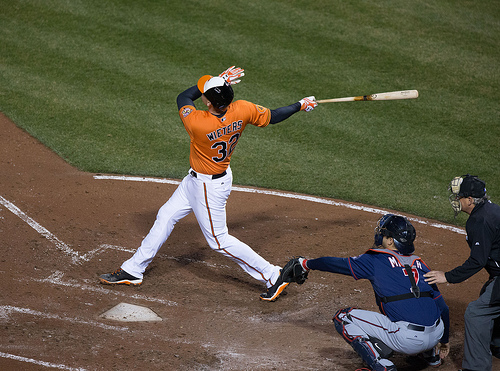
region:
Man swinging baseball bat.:
[273, 90, 402, 160]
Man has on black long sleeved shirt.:
[262, 102, 312, 155]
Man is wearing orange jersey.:
[186, 111, 245, 201]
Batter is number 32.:
[207, 112, 262, 226]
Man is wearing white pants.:
[166, 196, 241, 268]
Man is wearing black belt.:
[174, 161, 232, 211]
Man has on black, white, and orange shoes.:
[93, 255, 142, 312]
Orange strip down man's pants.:
[203, 188, 247, 323]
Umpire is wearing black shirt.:
[456, 196, 489, 314]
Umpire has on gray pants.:
[458, 292, 484, 344]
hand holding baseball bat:
[278, 48, 440, 150]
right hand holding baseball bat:
[281, 68, 446, 130]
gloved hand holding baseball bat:
[267, 68, 444, 145]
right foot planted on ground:
[85, 258, 152, 300]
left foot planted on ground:
[252, 248, 292, 324]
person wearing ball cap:
[192, 68, 238, 116]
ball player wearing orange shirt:
[166, 88, 278, 185]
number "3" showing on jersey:
[210, 136, 230, 172]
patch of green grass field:
[7, 2, 148, 131]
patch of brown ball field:
[14, 151, 79, 217]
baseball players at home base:
[81, 40, 453, 366]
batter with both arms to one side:
[130, 55, 435, 186]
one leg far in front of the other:
[86, 132, 286, 319]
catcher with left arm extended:
[252, 200, 443, 360]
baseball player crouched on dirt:
[270, 207, 456, 362]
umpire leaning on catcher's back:
[412, 125, 492, 360]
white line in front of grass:
[95, 162, 475, 264]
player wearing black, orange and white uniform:
[96, 40, 296, 317]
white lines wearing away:
[25, 227, 316, 362]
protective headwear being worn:
[437, 163, 492, 224]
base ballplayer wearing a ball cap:
[87, 39, 369, 285]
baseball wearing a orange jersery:
[85, 27, 397, 197]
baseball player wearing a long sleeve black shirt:
[50, 65, 388, 256]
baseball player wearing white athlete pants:
[28, 161, 293, 324]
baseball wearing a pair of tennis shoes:
[77, 41, 347, 287]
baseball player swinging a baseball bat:
[102, 25, 438, 305]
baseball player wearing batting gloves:
[78, 58, 338, 313]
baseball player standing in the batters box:
[0, 192, 306, 363]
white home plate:
[33, 252, 236, 348]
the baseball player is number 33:
[78, 60, 323, 231]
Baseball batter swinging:
[97, 61, 419, 299]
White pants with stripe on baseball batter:
[118, 167, 278, 282]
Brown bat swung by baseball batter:
[310, 85, 420, 107]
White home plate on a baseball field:
[98, 298, 163, 323]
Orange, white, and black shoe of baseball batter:
[97, 265, 142, 286]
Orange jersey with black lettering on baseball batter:
[175, 101, 271, 174]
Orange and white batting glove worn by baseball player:
[295, 92, 320, 112]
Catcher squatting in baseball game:
[277, 210, 448, 370]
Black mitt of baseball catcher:
[275, 253, 310, 288]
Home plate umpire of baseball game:
[421, 173, 498, 369]